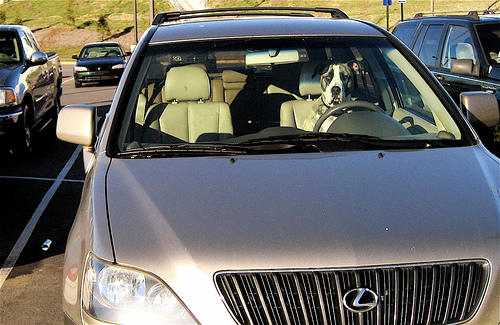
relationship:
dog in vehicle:
[301, 59, 364, 130] [57, 6, 499, 322]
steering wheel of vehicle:
[313, 102, 385, 134] [57, 6, 499, 322]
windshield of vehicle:
[108, 37, 472, 158] [57, 6, 499, 322]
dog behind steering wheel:
[301, 59, 364, 130] [313, 102, 385, 134]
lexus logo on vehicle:
[341, 287, 380, 314] [57, 6, 499, 322]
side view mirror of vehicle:
[55, 104, 99, 148] [57, 6, 499, 322]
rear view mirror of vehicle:
[244, 51, 299, 66] [57, 6, 499, 322]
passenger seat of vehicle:
[143, 61, 234, 144] [57, 6, 499, 322]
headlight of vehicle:
[84, 256, 200, 325] [57, 6, 499, 322]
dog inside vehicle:
[301, 59, 364, 130] [57, 6, 499, 322]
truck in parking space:
[1, 24, 61, 157] [0, 114, 99, 182]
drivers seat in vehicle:
[280, 64, 322, 127] [57, 6, 499, 322]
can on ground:
[40, 239, 49, 251] [0, 65, 126, 324]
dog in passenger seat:
[301, 59, 364, 130] [143, 61, 234, 144]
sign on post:
[381, 0, 392, 5] [386, 0, 389, 31]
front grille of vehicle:
[215, 258, 491, 324] [57, 6, 499, 322]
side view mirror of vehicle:
[459, 90, 499, 131] [57, 6, 499, 322]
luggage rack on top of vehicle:
[149, 4, 348, 26] [57, 6, 499, 322]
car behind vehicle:
[72, 43, 132, 86] [57, 6, 499, 322]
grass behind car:
[2, 0, 500, 60] [72, 43, 132, 86]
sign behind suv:
[381, 0, 392, 5] [392, 10, 499, 155]